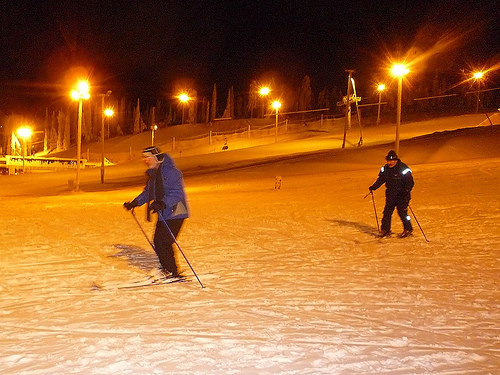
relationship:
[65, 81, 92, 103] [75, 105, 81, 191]
light on top of pole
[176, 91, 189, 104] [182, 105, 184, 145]
light on top of pole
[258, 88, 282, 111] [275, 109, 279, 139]
light on top of pole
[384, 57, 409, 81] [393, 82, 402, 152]
light on top of pole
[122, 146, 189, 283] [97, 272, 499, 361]
people going downhill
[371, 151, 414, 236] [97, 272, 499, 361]
skiier going downhill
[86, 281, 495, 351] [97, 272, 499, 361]
snow on slope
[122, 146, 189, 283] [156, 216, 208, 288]
people holding ski pole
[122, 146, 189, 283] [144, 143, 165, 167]
people wearing a hat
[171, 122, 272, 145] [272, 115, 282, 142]
fences near lamp post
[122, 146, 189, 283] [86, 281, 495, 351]
people on top of snow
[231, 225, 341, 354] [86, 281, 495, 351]
tracks on top of snow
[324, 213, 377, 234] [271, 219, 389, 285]
shadow on ground